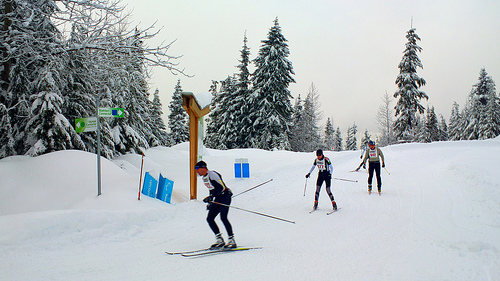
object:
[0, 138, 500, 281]
snow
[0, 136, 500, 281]
ground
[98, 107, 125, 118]
sign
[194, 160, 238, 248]
skier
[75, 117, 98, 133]
sign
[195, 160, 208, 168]
cap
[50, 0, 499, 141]
sky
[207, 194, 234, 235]
pants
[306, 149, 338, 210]
skier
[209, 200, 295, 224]
ski pole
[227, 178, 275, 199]
ski pole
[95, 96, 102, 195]
pole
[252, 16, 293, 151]
tree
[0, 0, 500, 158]
snow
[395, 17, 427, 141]
tree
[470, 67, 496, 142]
tree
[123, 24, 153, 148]
tree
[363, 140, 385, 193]
skier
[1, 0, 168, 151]
trees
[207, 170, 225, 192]
white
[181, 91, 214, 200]
mail box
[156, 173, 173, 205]
flag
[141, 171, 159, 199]
flag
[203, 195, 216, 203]
hand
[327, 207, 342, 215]
ski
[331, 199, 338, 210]
foot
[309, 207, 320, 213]
ski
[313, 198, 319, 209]
foot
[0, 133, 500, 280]
slope